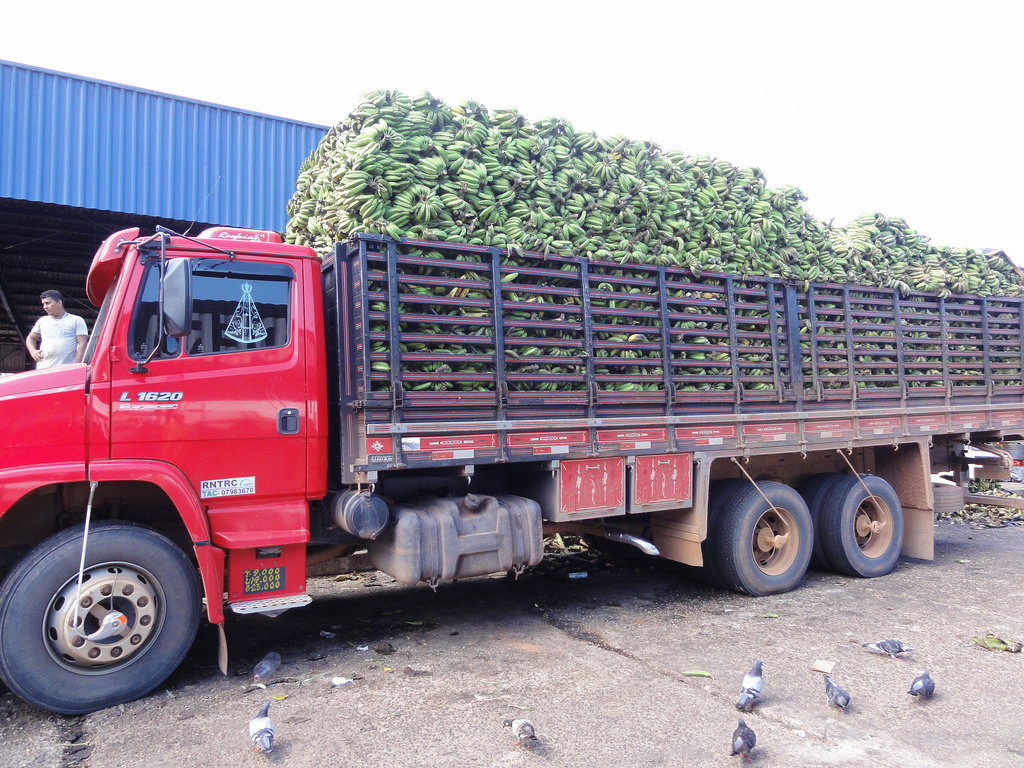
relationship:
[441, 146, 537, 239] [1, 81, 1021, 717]
banana in back of truck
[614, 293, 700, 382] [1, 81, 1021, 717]
banana in back of truck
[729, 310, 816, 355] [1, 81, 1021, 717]
banana in back of truck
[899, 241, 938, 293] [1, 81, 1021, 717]
banana in back of truck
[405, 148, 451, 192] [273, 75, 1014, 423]
banana bunch in trailer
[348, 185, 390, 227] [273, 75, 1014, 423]
banana bunch in trailer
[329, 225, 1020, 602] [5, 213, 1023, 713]
trailer behind truck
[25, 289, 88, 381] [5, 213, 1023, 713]
man standing next to truck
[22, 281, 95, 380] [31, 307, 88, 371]
man wearing shirt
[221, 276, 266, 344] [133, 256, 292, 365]
drawing visible on window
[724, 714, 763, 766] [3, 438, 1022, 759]
pigeon walking on ground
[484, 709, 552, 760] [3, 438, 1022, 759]
pigeon feeding on ground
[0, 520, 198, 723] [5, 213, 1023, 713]
tire on truck